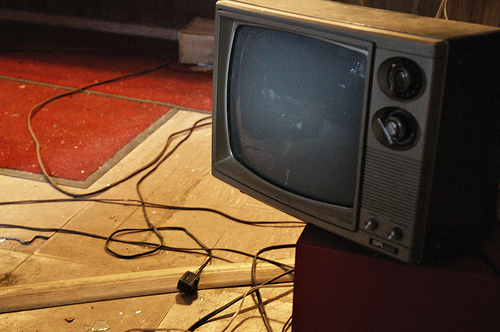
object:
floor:
[0, 110, 306, 332]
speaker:
[359, 147, 421, 226]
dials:
[386, 227, 401, 241]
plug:
[176, 270, 201, 293]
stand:
[290, 221, 499, 331]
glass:
[84, 309, 141, 331]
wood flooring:
[0, 108, 306, 331]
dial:
[364, 218, 378, 231]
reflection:
[243, 61, 366, 140]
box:
[177, 15, 214, 64]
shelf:
[0, 0, 180, 40]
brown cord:
[0, 58, 291, 329]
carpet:
[3, 49, 213, 192]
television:
[210, 1, 497, 262]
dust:
[230, 0, 499, 43]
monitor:
[227, 24, 372, 207]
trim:
[69, 96, 155, 179]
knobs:
[370, 55, 426, 150]